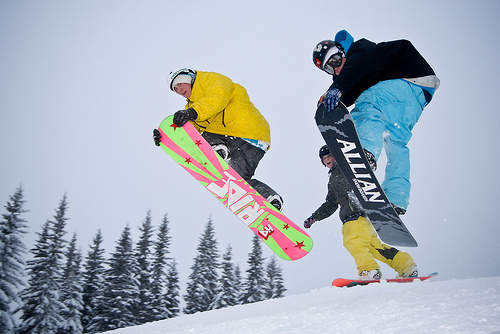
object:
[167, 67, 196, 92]
helmet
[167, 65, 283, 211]
person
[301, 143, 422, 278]
person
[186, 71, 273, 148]
jacket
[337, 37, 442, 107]
jacket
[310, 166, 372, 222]
jacket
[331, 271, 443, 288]
snowboard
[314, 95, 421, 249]
snowboard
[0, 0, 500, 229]
clouds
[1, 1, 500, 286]
sky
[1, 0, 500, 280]
blue sky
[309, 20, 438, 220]
person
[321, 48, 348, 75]
goggles